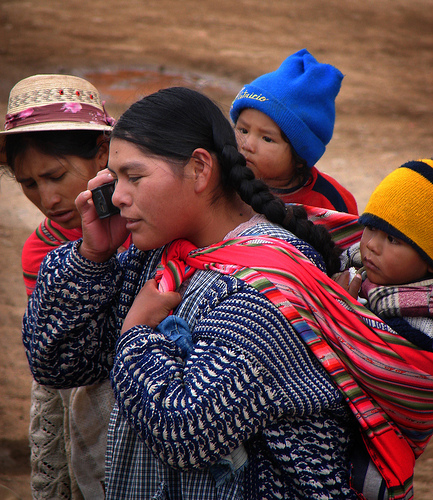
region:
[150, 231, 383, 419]
Pink fabric on a woman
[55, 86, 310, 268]
Woman on a phone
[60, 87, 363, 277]
Woman with dark hair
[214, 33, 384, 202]
Blue hat on a boy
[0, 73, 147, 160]
Straw hat on a boy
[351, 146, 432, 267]
Yellow hat on a boy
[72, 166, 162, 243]
Phone in a hand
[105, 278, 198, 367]
Woman holding fabric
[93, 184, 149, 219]
Nose on a woman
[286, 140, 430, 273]
Baby being carried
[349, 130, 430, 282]
a small child with a yellow and blue hat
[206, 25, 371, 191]
a small child with a blue hat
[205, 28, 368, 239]
a small child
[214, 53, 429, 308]
two small children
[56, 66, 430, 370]
a woman wearing a child on her back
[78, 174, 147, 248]
a black cell phone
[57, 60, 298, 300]
a woman talking on the phone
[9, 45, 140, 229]
a woman wearing a hat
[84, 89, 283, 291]
a woman with black hair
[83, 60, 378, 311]
a woman with her hair in a braid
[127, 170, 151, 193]
the eye of a person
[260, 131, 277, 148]
the eye of a person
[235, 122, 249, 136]
the eye of a person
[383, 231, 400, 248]
the eye of a person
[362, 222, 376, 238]
the eye of a person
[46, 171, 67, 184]
the eye of a person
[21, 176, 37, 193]
the eye of a person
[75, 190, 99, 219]
the finger of a person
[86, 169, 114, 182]
the finger of a person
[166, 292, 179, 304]
the finger of a person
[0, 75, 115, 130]
hat with a flower patterned band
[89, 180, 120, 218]
black cell phone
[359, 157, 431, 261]
yellow and navy knit hat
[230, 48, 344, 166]
blue knit hat with yellow embroidery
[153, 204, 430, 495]
sling made from fabric that holds a toddler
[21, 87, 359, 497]
woman with braided hair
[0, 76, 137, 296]
woman wearing a hat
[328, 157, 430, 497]
toddler in a sling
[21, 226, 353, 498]
blue and white sweater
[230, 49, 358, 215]
toddler with blue hat and red shirt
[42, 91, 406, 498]
woman on cell phone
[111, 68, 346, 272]
woman with braid in hair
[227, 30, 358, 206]
child with blue hat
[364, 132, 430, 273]
child with yellow hat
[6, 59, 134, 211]
woman with straw hat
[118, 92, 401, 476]
woman with red striped scarf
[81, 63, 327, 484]
woman in blue and white sweater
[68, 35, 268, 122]
mud puddle in photograph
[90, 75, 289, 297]
woman with no hat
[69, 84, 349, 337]
woman holding onto scarf